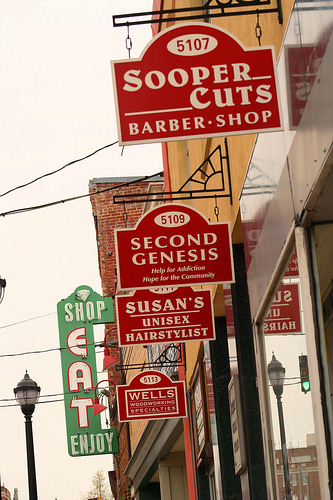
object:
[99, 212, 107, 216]
brick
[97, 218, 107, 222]
brick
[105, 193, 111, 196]
brick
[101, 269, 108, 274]
brick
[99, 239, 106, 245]
brick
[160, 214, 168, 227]
red numbers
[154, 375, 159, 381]
red numbers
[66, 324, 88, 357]
letters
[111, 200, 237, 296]
red sign2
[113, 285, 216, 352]
red sign3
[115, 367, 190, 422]
red sign4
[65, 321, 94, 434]
word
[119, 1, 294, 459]
yellow side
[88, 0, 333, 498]
building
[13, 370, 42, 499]
lamp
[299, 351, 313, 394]
traffic light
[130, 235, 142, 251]
letters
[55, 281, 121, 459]
sign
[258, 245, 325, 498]
reflection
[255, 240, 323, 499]
window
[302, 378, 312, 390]
light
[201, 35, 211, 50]
number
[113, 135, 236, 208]
hanger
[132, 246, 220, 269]
word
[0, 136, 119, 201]
wires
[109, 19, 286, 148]
sign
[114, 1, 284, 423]
row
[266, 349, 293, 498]
lamp